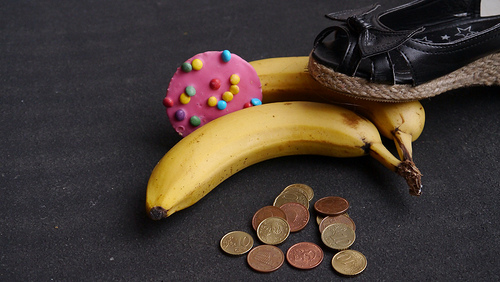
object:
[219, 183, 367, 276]
pennies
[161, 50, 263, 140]
frosting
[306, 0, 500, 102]
black shoe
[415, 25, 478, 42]
stars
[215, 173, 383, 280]
coins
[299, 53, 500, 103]
trim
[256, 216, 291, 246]
coin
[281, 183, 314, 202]
coin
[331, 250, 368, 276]
coin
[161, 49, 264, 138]
cupcake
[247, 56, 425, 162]
banana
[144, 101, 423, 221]
banana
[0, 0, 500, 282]
counter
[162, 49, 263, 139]
cookie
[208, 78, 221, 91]
sprinkle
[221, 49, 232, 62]
decoration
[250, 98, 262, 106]
decoration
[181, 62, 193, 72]
decoration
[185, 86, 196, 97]
decoration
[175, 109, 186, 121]
decoration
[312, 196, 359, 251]
coins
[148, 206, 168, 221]
bottom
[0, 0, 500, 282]
table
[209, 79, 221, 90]
candy topping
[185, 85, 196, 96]
sprinkle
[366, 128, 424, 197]
stem